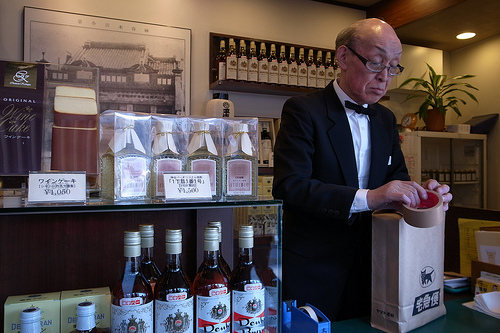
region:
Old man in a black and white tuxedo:
[275, 14, 416, 331]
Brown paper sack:
[368, 203, 446, 331]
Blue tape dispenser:
[288, 302, 328, 332]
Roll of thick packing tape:
[402, 188, 446, 230]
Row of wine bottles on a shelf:
[2, 212, 277, 329]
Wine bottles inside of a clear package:
[90, 106, 260, 201]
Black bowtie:
[335, 98, 371, 118]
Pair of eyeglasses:
[351, 50, 405, 80]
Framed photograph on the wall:
[15, 5, 191, 124]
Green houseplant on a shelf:
[391, 58, 481, 135]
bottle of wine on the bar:
[110, 229, 154, 331]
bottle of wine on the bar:
[154, 227, 194, 332]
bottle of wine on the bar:
[190, 227, 230, 332]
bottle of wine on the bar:
[230, 227, 263, 332]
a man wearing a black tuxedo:
[271, 18, 451, 320]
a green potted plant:
[400, 62, 478, 129]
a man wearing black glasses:
[273, 17, 451, 319]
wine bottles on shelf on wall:
[209, 30, 387, 99]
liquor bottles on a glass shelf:
[98, 110, 258, 204]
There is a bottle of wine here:
[241, 234, 266, 328]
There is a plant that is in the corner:
[429, 68, 446, 118]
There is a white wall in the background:
[193, 9, 199, 37]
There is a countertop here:
[450, 318, 454, 329]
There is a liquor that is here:
[117, 133, 146, 201]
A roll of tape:
[398, 182, 445, 228]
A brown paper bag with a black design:
[370, 201, 452, 329]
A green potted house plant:
[404, 57, 477, 129]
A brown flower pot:
[423, 105, 446, 131]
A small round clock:
[398, 110, 423, 130]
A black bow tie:
[341, 97, 385, 120]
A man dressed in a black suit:
[277, 12, 424, 326]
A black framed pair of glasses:
[341, 39, 408, 79]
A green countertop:
[327, 292, 497, 329]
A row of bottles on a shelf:
[212, 35, 348, 87]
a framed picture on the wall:
[21, 4, 193, 118]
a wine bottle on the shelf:
[111, 230, 153, 332]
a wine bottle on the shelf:
[153, 228, 194, 331]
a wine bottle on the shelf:
[191, 225, 231, 332]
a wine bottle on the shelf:
[230, 225, 265, 331]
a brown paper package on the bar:
[371, 206, 447, 331]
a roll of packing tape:
[400, 187, 442, 229]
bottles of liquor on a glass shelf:
[98, 112, 259, 204]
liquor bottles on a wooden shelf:
[209, 32, 391, 99]